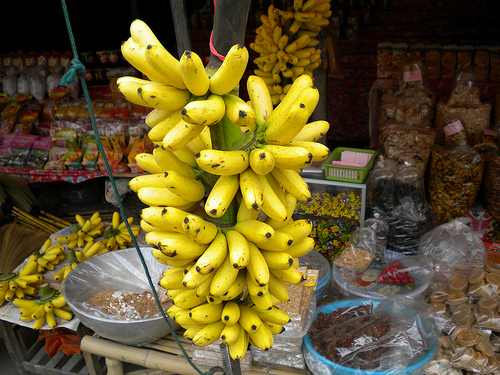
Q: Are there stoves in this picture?
A: No, there are no stoves.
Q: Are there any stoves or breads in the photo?
A: No, there are no stoves or breads.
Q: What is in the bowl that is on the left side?
A: The seasonings are in the bowl.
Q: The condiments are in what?
A: The condiments are in the bowl.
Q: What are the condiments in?
A: The condiments are in the bowl.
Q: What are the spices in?
A: The condiments are in the bowl.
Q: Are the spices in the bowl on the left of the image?
A: Yes, the spices are in the bowl.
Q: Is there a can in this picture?
A: No, there are no cans.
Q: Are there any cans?
A: No, there are no cans.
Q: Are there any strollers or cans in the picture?
A: No, there are no cans or strollers.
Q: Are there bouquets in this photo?
A: No, there are no bouquets.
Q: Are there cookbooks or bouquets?
A: No, there are no bouquets or cookbooks.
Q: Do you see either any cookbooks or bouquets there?
A: No, there are no bouquets or cookbooks.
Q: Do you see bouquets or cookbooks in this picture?
A: No, there are no bouquets or cookbooks.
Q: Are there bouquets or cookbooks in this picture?
A: No, there are no bouquets or cookbooks.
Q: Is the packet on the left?
A: Yes, the packet is on the left of the image.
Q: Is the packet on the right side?
A: No, the packet is on the left of the image.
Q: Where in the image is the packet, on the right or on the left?
A: The packet is on the left of the image.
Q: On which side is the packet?
A: The packet is on the left of the image.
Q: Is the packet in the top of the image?
A: Yes, the packet is in the top of the image.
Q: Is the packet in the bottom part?
A: No, the packet is in the top of the image.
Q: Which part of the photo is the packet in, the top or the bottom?
A: The packet is in the top of the image.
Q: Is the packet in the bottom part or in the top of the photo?
A: The packet is in the top of the image.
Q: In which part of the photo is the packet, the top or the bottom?
A: The packet is in the top of the image.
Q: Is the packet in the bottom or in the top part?
A: The packet is in the top of the image.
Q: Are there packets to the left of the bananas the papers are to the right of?
A: Yes, there is a packet to the left of the bananas.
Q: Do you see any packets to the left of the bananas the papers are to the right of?
A: Yes, there is a packet to the left of the bananas.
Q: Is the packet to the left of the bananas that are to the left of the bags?
A: Yes, the packet is to the left of the bananas.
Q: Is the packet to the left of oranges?
A: No, the packet is to the left of the bananas.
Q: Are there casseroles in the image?
A: No, there are no casseroles.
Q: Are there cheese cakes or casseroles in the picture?
A: No, there are no casseroles or cheese cakes.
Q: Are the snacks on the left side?
A: Yes, the snacks are on the left of the image.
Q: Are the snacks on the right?
A: No, the snacks are on the left of the image.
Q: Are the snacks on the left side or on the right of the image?
A: The snacks are on the left of the image.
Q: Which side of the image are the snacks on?
A: The snacks are on the left of the image.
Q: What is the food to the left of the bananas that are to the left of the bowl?
A: The food is snacks.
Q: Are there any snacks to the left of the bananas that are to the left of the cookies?
A: Yes, there are snacks to the left of the bananas.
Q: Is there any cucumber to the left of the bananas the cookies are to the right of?
A: No, there are snacks to the left of the bananas.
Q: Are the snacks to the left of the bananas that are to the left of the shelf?
A: Yes, the snacks are to the left of the bananas.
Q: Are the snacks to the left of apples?
A: No, the snacks are to the left of the bananas.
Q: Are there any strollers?
A: No, there are no strollers.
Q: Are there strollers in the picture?
A: No, there are no strollers.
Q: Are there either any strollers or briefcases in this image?
A: No, there are no strollers or briefcases.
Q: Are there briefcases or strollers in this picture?
A: No, there are no strollers or briefcases.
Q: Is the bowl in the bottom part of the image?
A: Yes, the bowl is in the bottom of the image.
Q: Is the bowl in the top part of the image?
A: No, the bowl is in the bottom of the image.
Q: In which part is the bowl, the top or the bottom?
A: The bowl is in the bottom of the image.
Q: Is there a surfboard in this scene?
A: No, there are no surfboards.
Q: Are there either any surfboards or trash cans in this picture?
A: No, there are no surfboards or trash cans.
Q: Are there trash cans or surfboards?
A: No, there are no surfboards or trash cans.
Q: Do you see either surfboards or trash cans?
A: No, there are no surfboards or trash cans.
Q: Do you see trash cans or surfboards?
A: No, there are no surfboards or trash cans.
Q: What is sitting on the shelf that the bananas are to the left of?
A: The basket is sitting on the shelf.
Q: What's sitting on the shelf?
A: The basket is sitting on the shelf.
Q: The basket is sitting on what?
A: The basket is sitting on the shelf.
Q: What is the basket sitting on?
A: The basket is sitting on the shelf.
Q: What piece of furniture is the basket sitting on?
A: The basket is sitting on the shelf.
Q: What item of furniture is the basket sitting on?
A: The basket is sitting on the shelf.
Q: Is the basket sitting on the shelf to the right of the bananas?
A: Yes, the basket is sitting on the shelf.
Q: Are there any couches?
A: No, there are no couches.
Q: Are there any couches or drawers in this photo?
A: No, there are no couches or drawers.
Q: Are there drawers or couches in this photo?
A: No, there are no couches or drawers.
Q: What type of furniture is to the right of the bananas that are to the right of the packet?
A: The piece of furniture is a shelf.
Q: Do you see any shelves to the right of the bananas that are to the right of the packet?
A: Yes, there is a shelf to the right of the bananas.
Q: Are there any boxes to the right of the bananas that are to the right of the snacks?
A: No, there is a shelf to the right of the bananas.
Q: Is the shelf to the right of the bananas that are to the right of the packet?
A: Yes, the shelf is to the right of the bananas.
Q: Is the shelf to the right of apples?
A: No, the shelf is to the right of the bananas.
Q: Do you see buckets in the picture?
A: No, there are no buckets.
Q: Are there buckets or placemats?
A: No, there are no buckets or placemats.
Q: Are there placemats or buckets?
A: No, there are no buckets or placemats.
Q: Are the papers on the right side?
A: Yes, the papers are on the right of the image.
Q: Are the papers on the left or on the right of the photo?
A: The papers are on the right of the image.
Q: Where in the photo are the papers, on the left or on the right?
A: The papers are on the right of the image.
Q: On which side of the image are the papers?
A: The papers are on the right of the image.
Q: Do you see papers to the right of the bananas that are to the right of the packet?
A: Yes, there are papers to the right of the bananas.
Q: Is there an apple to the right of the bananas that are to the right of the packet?
A: No, there are papers to the right of the bananas.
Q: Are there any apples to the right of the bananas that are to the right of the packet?
A: No, there are papers to the right of the bananas.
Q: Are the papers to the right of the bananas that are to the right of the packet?
A: Yes, the papers are to the right of the bananas.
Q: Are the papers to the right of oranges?
A: No, the papers are to the right of the bananas.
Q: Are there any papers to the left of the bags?
A: Yes, there are papers to the left of the bags.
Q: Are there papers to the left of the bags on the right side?
A: Yes, there are papers to the left of the bags.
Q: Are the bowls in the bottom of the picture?
A: Yes, the bowls are in the bottom of the image.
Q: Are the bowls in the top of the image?
A: No, the bowls are in the bottom of the image.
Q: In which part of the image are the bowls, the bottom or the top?
A: The bowls are in the bottom of the image.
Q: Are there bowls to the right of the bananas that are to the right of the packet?
A: Yes, there are bowls to the right of the bananas.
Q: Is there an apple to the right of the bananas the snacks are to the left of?
A: No, there are bowls to the right of the bananas.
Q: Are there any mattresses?
A: No, there are no mattresses.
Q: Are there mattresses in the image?
A: No, there are no mattresses.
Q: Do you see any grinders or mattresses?
A: No, there are no mattresses or grinders.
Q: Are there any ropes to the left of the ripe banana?
A: Yes, there is a rope to the left of the banana.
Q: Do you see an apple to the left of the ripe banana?
A: No, there is a rope to the left of the banana.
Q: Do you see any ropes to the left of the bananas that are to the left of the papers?
A: Yes, there is a rope to the left of the bananas.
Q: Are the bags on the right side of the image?
A: Yes, the bags are on the right of the image.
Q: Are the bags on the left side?
A: No, the bags are on the right of the image.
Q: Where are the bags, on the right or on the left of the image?
A: The bags are on the right of the image.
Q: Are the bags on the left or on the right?
A: The bags are on the right of the image.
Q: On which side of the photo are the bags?
A: The bags are on the right of the image.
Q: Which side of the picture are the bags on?
A: The bags are on the right of the image.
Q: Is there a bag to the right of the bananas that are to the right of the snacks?
A: Yes, there are bags to the right of the bananas.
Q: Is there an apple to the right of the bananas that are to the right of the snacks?
A: No, there are bags to the right of the bananas.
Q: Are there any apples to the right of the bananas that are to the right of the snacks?
A: No, there are bags to the right of the bananas.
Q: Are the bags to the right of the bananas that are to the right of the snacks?
A: Yes, the bags are to the right of the bananas.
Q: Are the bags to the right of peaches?
A: No, the bags are to the right of the bananas.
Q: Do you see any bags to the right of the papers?
A: Yes, there are bags to the right of the papers.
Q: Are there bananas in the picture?
A: Yes, there is a banana.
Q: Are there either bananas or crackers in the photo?
A: Yes, there is a banana.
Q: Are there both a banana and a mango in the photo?
A: No, there is a banana but no mangoes.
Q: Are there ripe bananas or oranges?
A: Yes, there is a ripe banana.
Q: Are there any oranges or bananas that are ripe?
A: Yes, the banana is ripe.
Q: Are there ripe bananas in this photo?
A: Yes, there is a ripe banana.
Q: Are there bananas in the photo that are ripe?
A: Yes, there is a banana that is ripe.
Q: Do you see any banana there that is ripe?
A: Yes, there is a banana that is ripe.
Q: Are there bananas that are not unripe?
A: Yes, there is an ripe banana.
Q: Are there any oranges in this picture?
A: No, there are no oranges.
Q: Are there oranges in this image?
A: No, there are no oranges.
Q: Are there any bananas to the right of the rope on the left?
A: Yes, there is a banana to the right of the rope.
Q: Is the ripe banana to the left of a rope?
A: Yes, the banana is to the left of a rope.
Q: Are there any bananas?
A: Yes, there are bananas.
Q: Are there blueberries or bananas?
A: Yes, there are bananas.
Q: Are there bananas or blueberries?
A: Yes, there are bananas.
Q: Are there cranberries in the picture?
A: No, there are no cranberries.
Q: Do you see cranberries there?
A: No, there are no cranberries.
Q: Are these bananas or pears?
A: These are bananas.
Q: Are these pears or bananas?
A: These are bananas.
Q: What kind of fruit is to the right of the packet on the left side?
A: The fruits are bananas.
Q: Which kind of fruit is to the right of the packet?
A: The fruits are bananas.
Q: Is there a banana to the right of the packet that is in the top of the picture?
A: Yes, there are bananas to the right of the packet.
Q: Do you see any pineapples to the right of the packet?
A: No, there are bananas to the right of the packet.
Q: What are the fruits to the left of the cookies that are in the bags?
A: The fruits are bananas.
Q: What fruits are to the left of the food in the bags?
A: The fruits are bananas.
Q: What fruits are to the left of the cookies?
A: The fruits are bananas.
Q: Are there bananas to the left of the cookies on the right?
A: Yes, there are bananas to the left of the cookies.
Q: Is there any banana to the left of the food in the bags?
A: Yes, there are bananas to the left of the cookies.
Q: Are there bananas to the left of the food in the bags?
A: Yes, there are bananas to the left of the cookies.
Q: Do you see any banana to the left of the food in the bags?
A: Yes, there are bananas to the left of the cookies.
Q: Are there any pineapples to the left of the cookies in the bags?
A: No, there are bananas to the left of the cookies.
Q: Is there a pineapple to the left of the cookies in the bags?
A: No, there are bananas to the left of the cookies.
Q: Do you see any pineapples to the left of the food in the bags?
A: No, there are bananas to the left of the cookies.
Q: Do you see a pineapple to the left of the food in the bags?
A: No, there are bananas to the left of the cookies.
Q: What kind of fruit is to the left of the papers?
A: The fruits are bananas.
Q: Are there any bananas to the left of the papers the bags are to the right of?
A: Yes, there are bananas to the left of the papers.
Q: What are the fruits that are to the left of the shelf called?
A: The fruits are bananas.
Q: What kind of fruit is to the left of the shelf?
A: The fruits are bananas.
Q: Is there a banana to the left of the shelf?
A: Yes, there are bananas to the left of the shelf.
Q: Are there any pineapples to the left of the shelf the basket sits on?
A: No, there are bananas to the left of the shelf.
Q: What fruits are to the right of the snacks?
A: The fruits are bananas.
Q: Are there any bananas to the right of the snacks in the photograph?
A: Yes, there are bananas to the right of the snacks.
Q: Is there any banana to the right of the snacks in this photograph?
A: Yes, there are bananas to the right of the snacks.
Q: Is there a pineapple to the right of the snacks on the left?
A: No, there are bananas to the right of the snacks.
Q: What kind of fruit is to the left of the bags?
A: The fruits are bananas.